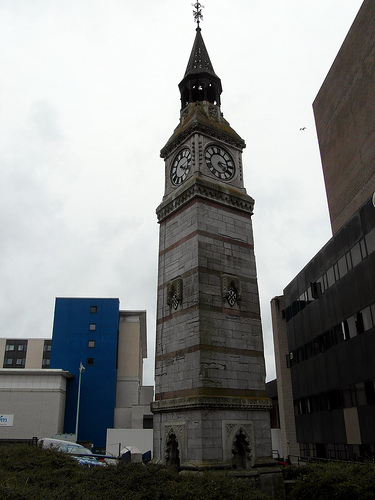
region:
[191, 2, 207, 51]
point on top of tower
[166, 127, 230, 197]
clock near top of tower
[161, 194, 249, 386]
tower is grey brick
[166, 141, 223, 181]
roman numerals on clock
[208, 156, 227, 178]
white face on clock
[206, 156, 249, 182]
black hands on clock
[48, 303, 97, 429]
blue wall on building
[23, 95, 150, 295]
sky is cloudy and grey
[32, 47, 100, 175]
thick clouds in sky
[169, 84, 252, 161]
brown roof on tower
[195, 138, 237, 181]
rounds clock face on tower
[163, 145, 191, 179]
rounds clock face on tower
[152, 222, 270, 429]
stone brick wall on tower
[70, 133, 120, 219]
gray overcast skies above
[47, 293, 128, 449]
blue wall on side of building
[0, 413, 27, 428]
white sign on side of building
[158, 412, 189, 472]
archway on side of building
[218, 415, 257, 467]
archway on side of building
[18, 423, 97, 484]
blue vehicle on left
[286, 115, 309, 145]
small bird flying in air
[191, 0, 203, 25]
A metal weather vane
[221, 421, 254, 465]
Entrance to the tower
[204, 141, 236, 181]
Clock on the tower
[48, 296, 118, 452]
The wall is blue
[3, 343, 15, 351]
A window on the building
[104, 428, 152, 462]
The wall is beige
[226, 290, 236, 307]
Shield on the wall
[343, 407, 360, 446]
Light brown panel on building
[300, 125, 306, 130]
A bird is flying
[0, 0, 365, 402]
The weather is cloudy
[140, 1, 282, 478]
A tall stone spire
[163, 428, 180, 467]
Archway into the tower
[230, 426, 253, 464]
Arch has alternating colors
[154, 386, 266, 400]
Brown stripe on tower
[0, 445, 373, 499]
Ground is covered in grass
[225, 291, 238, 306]
Shield on the window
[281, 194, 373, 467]
The building is brown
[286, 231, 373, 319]
A row of windows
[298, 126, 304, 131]
Bird in the sky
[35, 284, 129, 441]
a blue rectangle wall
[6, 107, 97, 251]
the sky is overcast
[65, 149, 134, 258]
the sky is overcast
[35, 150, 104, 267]
the sky is overcast